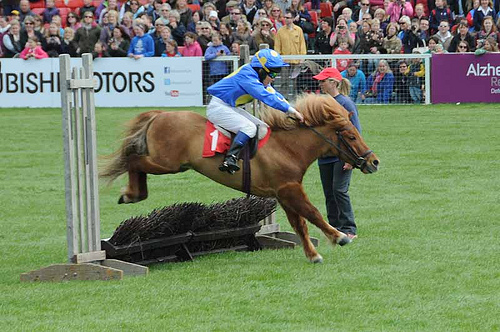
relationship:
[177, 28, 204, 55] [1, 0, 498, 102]
person in audience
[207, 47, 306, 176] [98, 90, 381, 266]
rider on horse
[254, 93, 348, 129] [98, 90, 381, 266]
mane on horse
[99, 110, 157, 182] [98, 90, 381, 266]
tail on horse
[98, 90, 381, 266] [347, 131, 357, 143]
horse has eye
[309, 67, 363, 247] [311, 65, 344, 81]
person wears hat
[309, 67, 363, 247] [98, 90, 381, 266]
person near horse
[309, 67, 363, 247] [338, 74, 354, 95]
person has ponytail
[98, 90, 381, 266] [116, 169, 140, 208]
horse has leg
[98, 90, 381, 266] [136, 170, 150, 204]
horse has leg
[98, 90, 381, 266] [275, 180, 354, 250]
horse has leg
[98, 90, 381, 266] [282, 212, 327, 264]
horse has leg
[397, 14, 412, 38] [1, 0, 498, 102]
person in audience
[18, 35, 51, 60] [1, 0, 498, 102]
person in audience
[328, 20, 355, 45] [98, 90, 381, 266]
person watches horse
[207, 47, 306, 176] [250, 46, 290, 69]
rider wearing helmet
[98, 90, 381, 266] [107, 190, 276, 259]
horse jumps over item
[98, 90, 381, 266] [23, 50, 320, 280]
horse jumps fence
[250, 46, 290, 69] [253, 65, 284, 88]
helmet on head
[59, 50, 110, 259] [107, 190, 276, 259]
gate around jump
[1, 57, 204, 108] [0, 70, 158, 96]
sign has lettering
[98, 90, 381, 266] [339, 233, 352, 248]
horse has hoof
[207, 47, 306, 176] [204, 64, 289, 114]
rider wearing shirt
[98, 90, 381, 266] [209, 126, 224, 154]
horse wears number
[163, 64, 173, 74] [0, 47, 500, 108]
logo on fence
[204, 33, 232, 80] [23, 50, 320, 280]
person behind fence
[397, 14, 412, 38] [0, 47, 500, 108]
person behind fence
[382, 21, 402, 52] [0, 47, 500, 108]
spectator behind fence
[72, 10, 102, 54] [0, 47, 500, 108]
spectator behind fence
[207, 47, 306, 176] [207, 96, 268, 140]
rider wears pants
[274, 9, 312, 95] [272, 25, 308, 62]
man wearing shirt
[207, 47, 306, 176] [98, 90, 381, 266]
rider rides horse